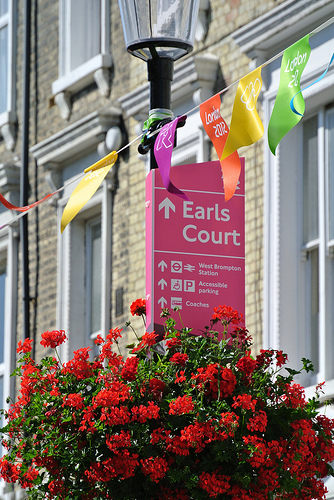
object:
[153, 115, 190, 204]
banner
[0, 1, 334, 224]
line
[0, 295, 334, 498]
bush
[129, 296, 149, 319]
flower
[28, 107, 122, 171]
cornice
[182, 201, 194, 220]
letter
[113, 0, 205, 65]
lamp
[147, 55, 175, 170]
pole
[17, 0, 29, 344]
downspout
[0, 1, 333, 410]
building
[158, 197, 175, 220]
arrow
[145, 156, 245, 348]
sign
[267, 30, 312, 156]
pennant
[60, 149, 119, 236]
flag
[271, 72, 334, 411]
window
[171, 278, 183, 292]
logo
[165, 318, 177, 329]
leaf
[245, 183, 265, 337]
brick